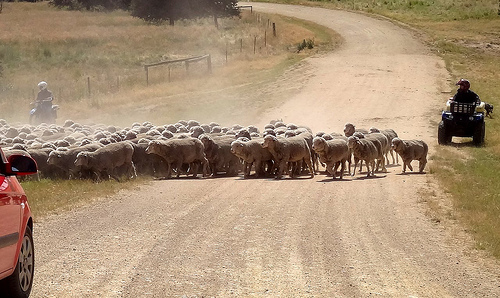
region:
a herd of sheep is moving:
[0, 120, 432, 181]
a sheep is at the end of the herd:
[390, 137, 430, 172]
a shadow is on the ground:
[398, 169, 434, 174]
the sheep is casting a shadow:
[391, 135, 436, 179]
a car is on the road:
[0, 149, 40, 296]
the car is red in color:
[1, 147, 34, 284]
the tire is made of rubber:
[13, 232, 38, 294]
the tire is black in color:
[10, 230, 36, 295]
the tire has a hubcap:
[16, 235, 36, 290]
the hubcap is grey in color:
[16, 238, 33, 290]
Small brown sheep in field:
[348, 129, 379, 184]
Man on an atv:
[418, 49, 465, 139]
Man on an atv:
[27, 74, 67, 135]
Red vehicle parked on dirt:
[1, 106, 53, 296]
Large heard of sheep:
[7, 113, 427, 184]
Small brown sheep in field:
[263, 128, 313, 185]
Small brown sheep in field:
[149, 131, 211, 181]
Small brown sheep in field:
[78, 140, 133, 171]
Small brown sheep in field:
[320, 136, 348, 178]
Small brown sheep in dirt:
[393, 129, 450, 181]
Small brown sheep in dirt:
[349, 131, 375, 179]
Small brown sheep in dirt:
[260, 119, 307, 176]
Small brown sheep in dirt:
[233, 122, 265, 183]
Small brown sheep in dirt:
[155, 129, 239, 179]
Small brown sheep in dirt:
[75, 140, 139, 180]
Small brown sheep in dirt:
[51, 138, 92, 178]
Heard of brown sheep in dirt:
[28, 109, 426, 191]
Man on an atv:
[431, 71, 486, 164]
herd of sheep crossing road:
[72, 103, 430, 188]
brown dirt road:
[105, 194, 432, 296]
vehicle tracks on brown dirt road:
[273, 213, 415, 296]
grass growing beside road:
[447, 156, 498, 236]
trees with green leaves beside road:
[139, 0, 238, 28]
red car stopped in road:
[0, 146, 56, 288]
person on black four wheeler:
[418, 69, 495, 161]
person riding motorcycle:
[18, 71, 69, 130]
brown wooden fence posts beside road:
[130, 51, 215, 87]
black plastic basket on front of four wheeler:
[445, 97, 481, 119]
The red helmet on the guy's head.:
[454, 78, 471, 93]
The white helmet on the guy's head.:
[35, 78, 46, 89]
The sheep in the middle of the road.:
[11, 118, 427, 174]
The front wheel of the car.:
[11, 225, 41, 288]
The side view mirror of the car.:
[3, 146, 43, 176]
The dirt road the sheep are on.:
[37, 8, 457, 295]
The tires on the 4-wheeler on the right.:
[436, 116, 486, 146]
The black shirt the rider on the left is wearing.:
[34, 93, 51, 103]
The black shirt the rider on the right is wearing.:
[454, 92, 476, 101]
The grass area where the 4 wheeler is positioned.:
[439, 73, 499, 217]